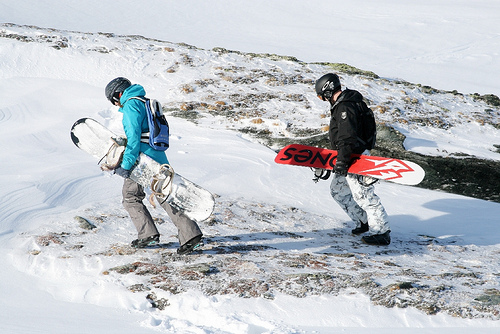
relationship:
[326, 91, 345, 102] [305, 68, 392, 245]
neck of man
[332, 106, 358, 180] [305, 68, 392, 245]
arm of man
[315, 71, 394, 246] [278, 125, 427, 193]
man with snowboard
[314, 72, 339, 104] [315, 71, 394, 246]
head of man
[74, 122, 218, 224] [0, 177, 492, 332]
snowboard with snow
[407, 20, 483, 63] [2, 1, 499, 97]
clouds in sky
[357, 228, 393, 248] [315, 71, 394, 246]
foot of a man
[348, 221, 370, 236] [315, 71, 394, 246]
foot of a man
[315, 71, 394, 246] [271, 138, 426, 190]
man wearing pants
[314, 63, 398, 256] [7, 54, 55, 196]
man in snow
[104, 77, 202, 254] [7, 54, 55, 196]
man in snow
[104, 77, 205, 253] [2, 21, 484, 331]
man in snow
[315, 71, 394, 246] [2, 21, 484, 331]
man in snow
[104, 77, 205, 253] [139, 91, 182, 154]
man wears backpack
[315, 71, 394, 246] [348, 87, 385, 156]
man wears backpack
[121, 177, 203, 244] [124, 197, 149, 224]
man`s pant has part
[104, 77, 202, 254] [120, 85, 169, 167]
man has jacket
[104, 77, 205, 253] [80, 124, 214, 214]
man with snowboard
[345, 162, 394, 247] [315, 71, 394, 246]
leg belonging to man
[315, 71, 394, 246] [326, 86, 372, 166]
man wearing coat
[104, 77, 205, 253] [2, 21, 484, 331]
man walking on snow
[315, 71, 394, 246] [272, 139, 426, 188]
man carrying snowboard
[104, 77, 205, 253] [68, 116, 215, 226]
man carrying snowboard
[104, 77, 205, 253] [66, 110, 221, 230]
man holding snowboard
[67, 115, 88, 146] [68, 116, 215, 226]
part belonging to snowboard